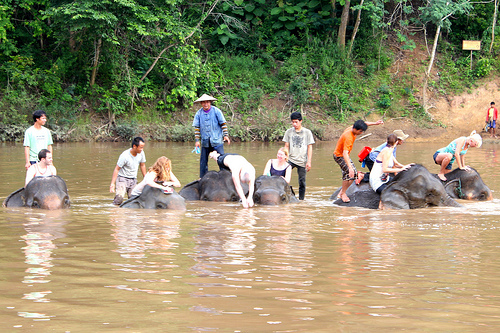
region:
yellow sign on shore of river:
[455, 34, 487, 57]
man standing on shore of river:
[473, 94, 498, 128]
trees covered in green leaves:
[8, 0, 188, 98]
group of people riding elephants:
[13, 112, 498, 231]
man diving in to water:
[203, 150, 265, 211]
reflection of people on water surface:
[64, 214, 318, 284]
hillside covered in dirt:
[402, 50, 422, 73]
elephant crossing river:
[10, 175, 76, 217]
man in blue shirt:
[186, 86, 233, 148]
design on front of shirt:
[289, 130, 307, 147]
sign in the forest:
[460, 36, 481, 73]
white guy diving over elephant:
[207, 149, 255, 211]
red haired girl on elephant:
[130, 158, 178, 198]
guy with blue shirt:
[190, 95, 228, 170]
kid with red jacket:
[484, 100, 496, 136]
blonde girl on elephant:
[427, 130, 480, 182]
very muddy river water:
[16, 232, 478, 324]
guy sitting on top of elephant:
[8, 150, 70, 214]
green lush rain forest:
[6, 15, 351, 80]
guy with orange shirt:
[330, 120, 360, 204]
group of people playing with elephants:
[11, 83, 498, 205]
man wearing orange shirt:
[327, 116, 371, 209]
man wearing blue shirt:
[174, 81, 239, 181]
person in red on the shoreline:
[482, 101, 499, 118]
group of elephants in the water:
[6, 171, 496, 211]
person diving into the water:
[217, 146, 269, 210]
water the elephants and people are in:
[2, 138, 497, 329]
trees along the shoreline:
[2, 1, 461, 117]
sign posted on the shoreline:
[455, 36, 490, 80]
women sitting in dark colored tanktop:
[260, 145, 296, 195]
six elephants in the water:
[6, 164, 492, 231]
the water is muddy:
[11, 215, 490, 327]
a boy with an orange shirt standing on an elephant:
[333, 112, 363, 206]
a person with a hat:
[185, 77, 233, 174]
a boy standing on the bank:
[482, 95, 498, 138]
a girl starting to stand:
[428, 127, 483, 179]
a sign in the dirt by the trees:
[453, 30, 485, 80]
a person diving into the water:
[205, 147, 262, 212]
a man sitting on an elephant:
[19, 144, 67, 182]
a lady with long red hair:
[142, 146, 180, 196]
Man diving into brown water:
[212, 147, 258, 214]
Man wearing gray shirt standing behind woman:
[279, 111, 313, 200]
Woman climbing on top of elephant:
[433, 130, 483, 177]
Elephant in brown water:
[5, 175, 72, 214]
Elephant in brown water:
[112, 184, 187, 214]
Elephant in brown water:
[182, 170, 246, 202]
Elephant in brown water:
[253, 171, 295, 208]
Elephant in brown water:
[326, 161, 458, 209]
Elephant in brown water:
[430, 165, 492, 202]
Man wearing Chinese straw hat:
[190, 90, 231, 172]